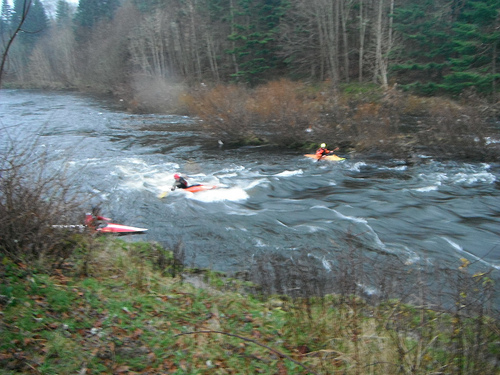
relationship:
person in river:
[172, 174, 190, 193] [0, 87, 499, 316]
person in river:
[316, 142, 334, 162] [0, 87, 499, 316]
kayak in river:
[305, 153, 346, 161] [0, 87, 499, 316]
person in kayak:
[316, 142, 334, 162] [305, 153, 346, 161]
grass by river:
[185, 81, 499, 160] [0, 87, 499, 316]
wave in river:
[69, 155, 305, 202] [0, 87, 499, 316]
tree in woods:
[207, 3, 298, 89] [0, 0, 499, 162]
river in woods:
[0, 87, 499, 316] [0, 0, 499, 162]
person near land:
[84, 206, 112, 230] [0, 193, 499, 375]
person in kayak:
[172, 174, 190, 193] [178, 183, 220, 193]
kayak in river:
[48, 222, 149, 234] [0, 87, 499, 316]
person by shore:
[84, 206, 112, 230] [1, 203, 500, 375]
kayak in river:
[178, 183, 220, 193] [0, 87, 499, 316]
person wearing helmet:
[316, 142, 334, 162] [319, 142, 327, 148]